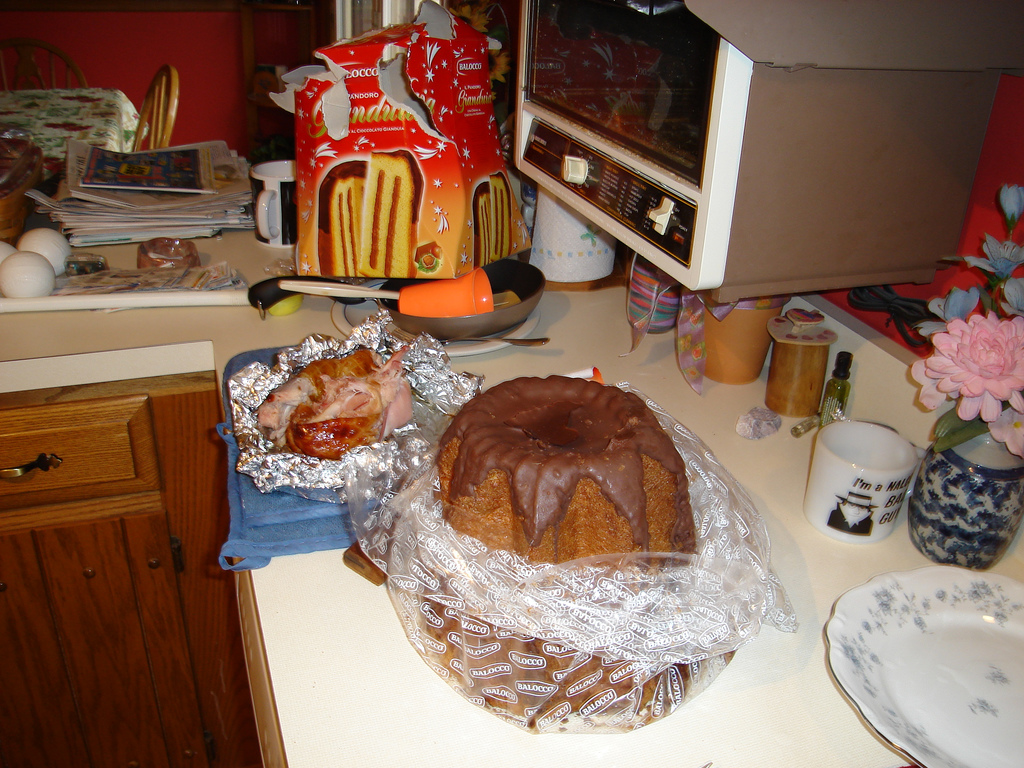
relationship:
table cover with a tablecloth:
[41, 95, 115, 135] [8, 80, 164, 173]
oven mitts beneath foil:
[216, 409, 364, 587] [214, 310, 478, 499]